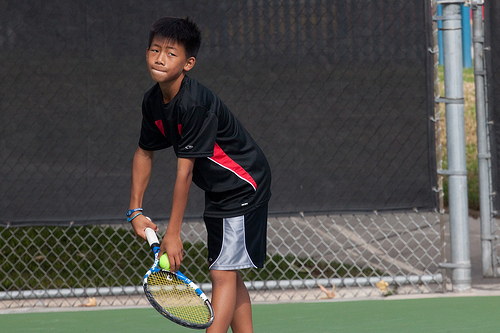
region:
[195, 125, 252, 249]
this is a boy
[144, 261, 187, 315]
this is a racket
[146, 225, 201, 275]
this is a ball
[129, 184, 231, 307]
the ball is for tennis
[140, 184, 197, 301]
the ball is green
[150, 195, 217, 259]
this is an arm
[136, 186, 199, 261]
this is a wrist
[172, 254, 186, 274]
this is a hand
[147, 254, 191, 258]
these are some fingers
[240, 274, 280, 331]
this is a leg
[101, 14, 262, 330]
the boy on the court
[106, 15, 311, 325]
the boy is serving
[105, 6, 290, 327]
the boy holding the racquet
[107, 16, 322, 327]
the boy holding the ball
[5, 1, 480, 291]
chain link fence behind boy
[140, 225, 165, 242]
handle of the racquet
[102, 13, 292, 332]
the boy playing tennis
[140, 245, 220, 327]
the racquet is blue and white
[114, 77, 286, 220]
boy wearing black and red t shirt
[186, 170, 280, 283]
boy wearing black and silver shorts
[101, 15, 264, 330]
boy is holding a racket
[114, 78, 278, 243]
the shirt is black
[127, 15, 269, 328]
a boy playing tennis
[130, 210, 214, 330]
a boy about to serve a ball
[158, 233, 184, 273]
a boy holding a tennis ball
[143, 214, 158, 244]
white handle of a tennis racket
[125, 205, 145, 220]
boy wearing two blue bracelets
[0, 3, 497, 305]
a metal fence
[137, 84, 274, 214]
a black shirt with a red line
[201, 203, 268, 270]
black and silver shorts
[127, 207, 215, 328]
by holding a tennis racket and a ball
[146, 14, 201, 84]
boy with short black hair